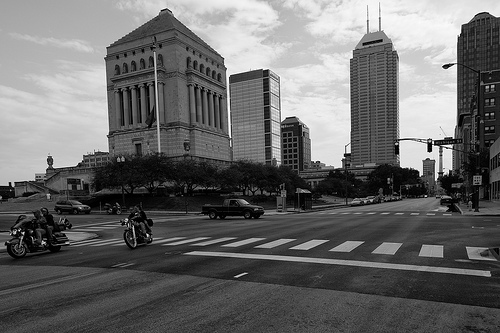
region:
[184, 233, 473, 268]
white marking in a crosswalk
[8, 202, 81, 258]
a couple riding on a microwave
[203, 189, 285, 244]
a truck crossing the intersection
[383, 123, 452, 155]
a traffic light above the street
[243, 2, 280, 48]
clouds floating in the sky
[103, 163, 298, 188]
trees surrounding the building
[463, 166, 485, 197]
a traffic sign on the sidewalk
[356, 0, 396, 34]
antennas on top of a building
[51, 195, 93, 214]
a van parked on the curb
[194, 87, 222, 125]
stone columns on a building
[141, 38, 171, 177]
Tall white flag pole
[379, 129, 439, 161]
hanging stop lights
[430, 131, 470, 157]
Street sign on pole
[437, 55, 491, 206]
Tall street light pole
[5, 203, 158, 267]
Pair of motorcycles with two riders each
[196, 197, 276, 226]
a pickup truck in motion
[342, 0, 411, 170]
Tall building with two spires on top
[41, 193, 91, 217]
Minivan parked on side of road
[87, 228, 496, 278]
Nearest crosswalk painted in white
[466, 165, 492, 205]
One Way street sign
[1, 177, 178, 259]
Motorcycles on the road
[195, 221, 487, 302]
Crosswalk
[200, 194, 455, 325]
An intersection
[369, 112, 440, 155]
Traffic lights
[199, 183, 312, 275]
A truck in the intersection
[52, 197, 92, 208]
A parked vehicle on the side of the street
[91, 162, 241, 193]
Trees by the street curb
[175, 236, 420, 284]
A white line on the roadway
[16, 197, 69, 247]
Two people riding the motorcycle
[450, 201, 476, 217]
Sidewalk corner near the intersection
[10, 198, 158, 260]
two motorcycles in the street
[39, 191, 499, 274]
three long crosswalks painted in white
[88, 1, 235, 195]
an old style building with many pillars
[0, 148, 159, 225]
long steps leading up to an old building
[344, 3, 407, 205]
a tall skyscraper with two radio antennae on top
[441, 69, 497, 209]
an apartment building with many windows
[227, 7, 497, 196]
several skyscrapers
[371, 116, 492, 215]
a traffic light overhead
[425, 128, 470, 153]
a street sign on a traffic light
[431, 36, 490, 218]
a modern style street light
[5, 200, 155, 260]
two motorcycles riding tandem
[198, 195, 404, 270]
a pickup truck in the intersection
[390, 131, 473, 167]
two signal lights in the intersection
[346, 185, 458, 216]
cars parked on the side of the street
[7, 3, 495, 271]
tall buildings in the background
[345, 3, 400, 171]
the building has two antennas on top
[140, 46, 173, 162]
the flag is flown at half mast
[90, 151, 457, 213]
trees line the street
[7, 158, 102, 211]
a staircase into a building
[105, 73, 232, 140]
columns are on a stately building